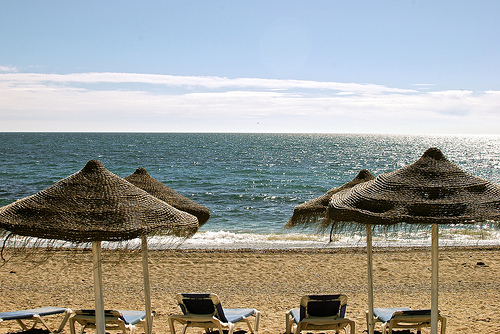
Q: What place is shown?
A: It is a beach.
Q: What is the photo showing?
A: It is showing a beach.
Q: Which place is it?
A: It is a beach.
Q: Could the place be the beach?
A: Yes, it is the beach.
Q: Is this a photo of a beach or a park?
A: It is showing a beach.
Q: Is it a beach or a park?
A: It is a beach.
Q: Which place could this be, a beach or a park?
A: It is a beach.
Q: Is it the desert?
A: No, it is the beach.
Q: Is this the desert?
A: No, it is the beach.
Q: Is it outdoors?
A: Yes, it is outdoors.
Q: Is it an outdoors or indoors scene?
A: It is outdoors.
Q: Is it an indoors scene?
A: No, it is outdoors.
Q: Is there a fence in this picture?
A: No, there are no fences.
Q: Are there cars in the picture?
A: No, there are no cars.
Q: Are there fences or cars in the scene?
A: No, there are no cars or fences.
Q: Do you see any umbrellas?
A: Yes, there is an umbrella.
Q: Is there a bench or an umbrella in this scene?
A: Yes, there is an umbrella.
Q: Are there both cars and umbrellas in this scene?
A: No, there is an umbrella but no cars.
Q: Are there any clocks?
A: No, there are no clocks.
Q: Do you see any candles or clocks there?
A: No, there are no clocks or candles.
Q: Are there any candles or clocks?
A: No, there are no clocks or candles.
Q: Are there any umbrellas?
A: Yes, there is an umbrella.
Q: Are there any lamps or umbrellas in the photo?
A: Yes, there is an umbrella.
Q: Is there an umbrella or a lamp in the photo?
A: Yes, there is an umbrella.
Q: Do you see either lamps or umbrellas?
A: Yes, there is an umbrella.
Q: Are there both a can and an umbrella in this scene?
A: No, there is an umbrella but no cans.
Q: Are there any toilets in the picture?
A: No, there are no toilets.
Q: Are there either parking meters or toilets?
A: No, there are no toilets or parking meters.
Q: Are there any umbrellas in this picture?
A: Yes, there is an umbrella.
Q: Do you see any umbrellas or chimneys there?
A: Yes, there is an umbrella.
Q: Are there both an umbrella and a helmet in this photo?
A: No, there is an umbrella but no helmets.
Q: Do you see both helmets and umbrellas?
A: No, there is an umbrella but no helmets.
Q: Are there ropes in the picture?
A: No, there are no ropes.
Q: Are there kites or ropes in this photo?
A: No, there are no ropes or kites.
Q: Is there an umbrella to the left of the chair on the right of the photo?
A: Yes, there is an umbrella to the left of the chair.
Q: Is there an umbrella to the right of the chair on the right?
A: No, the umbrella is to the left of the chair.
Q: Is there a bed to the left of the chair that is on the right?
A: No, there is an umbrella to the left of the chair.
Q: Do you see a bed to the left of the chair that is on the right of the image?
A: No, there is an umbrella to the left of the chair.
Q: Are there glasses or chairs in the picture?
A: Yes, there is a chair.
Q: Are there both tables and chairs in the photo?
A: No, there is a chair but no tables.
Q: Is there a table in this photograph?
A: No, there are no tables.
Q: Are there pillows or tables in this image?
A: No, there are no tables or pillows.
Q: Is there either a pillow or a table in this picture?
A: No, there are no tables or pillows.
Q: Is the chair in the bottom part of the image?
A: Yes, the chair is in the bottom of the image.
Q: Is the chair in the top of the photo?
A: No, the chair is in the bottom of the image.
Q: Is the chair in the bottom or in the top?
A: The chair is in the bottom of the image.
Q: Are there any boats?
A: No, there are no boats.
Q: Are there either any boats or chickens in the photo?
A: No, there are no boats or chickens.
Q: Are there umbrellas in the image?
A: Yes, there is an umbrella.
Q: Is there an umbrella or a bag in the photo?
A: Yes, there is an umbrella.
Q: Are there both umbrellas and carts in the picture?
A: No, there is an umbrella but no carts.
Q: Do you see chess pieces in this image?
A: No, there are no chess pieces.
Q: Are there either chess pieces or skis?
A: No, there are no chess pieces or skis.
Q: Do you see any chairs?
A: Yes, there is a chair.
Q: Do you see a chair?
A: Yes, there is a chair.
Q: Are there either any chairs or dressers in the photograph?
A: Yes, there is a chair.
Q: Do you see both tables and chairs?
A: No, there is a chair but no tables.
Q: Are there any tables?
A: No, there are no tables.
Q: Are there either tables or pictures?
A: No, there are no tables or pictures.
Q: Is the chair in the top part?
A: No, the chair is in the bottom of the image.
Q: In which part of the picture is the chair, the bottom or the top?
A: The chair is in the bottom of the image.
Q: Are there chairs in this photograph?
A: Yes, there is a chair.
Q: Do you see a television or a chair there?
A: Yes, there is a chair.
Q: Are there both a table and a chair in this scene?
A: No, there is a chair but no tables.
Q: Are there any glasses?
A: No, there are no glasses.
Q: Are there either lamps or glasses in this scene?
A: No, there are no glasses or lamps.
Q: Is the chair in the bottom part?
A: Yes, the chair is in the bottom of the image.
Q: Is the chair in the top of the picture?
A: No, the chair is in the bottom of the image.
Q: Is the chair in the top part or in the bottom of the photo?
A: The chair is in the bottom of the image.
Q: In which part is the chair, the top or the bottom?
A: The chair is in the bottom of the image.